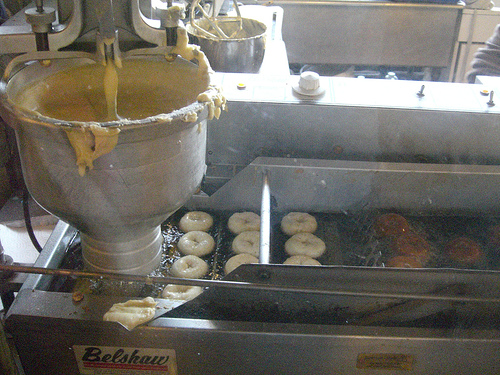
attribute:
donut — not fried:
[180, 207, 213, 233]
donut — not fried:
[226, 204, 261, 234]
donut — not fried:
[281, 207, 318, 236]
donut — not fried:
[283, 230, 328, 257]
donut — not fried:
[231, 227, 263, 254]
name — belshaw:
[74, 335, 178, 373]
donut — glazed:
[393, 234, 438, 256]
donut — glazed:
[444, 232, 479, 265]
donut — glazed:
[376, 209, 411, 236]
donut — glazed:
[387, 253, 422, 268]